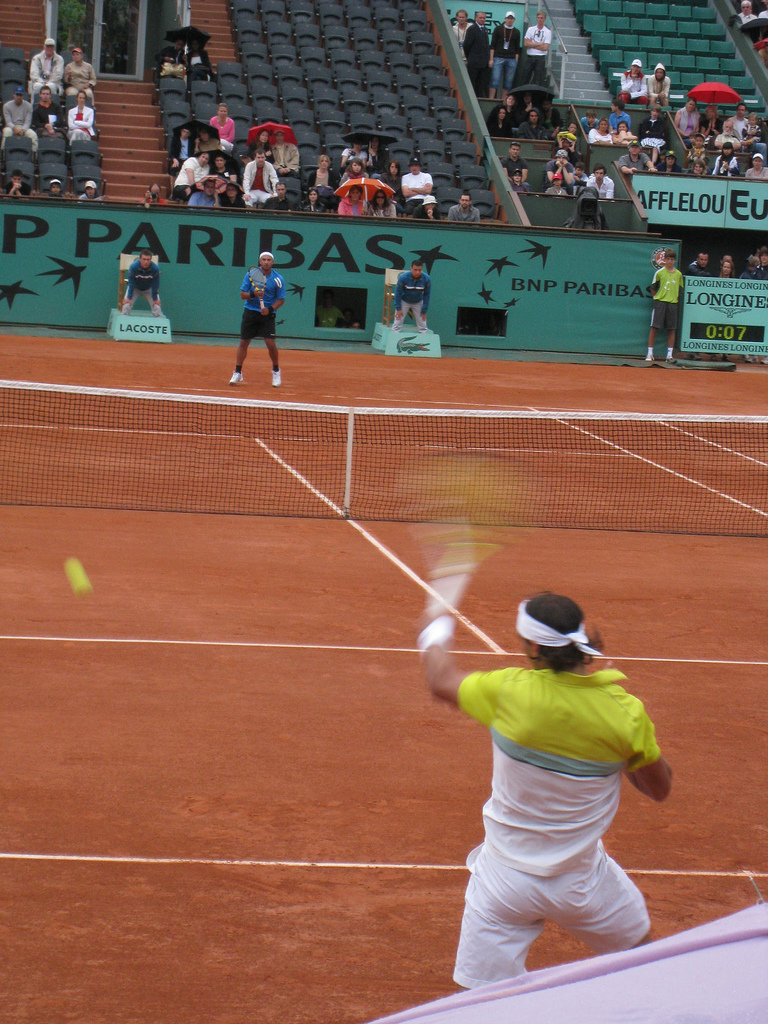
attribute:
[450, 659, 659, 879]
shirt — yellow, white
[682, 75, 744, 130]
umbrella — red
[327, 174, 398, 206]
umbrella — red, white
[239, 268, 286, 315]
shirt — blue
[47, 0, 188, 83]
door — glass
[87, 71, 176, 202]
stairs — red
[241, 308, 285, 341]
shorts — black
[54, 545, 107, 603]
tennis ball — flying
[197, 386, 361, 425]
edge — white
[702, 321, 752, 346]
timer — digital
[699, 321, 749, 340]
numbers — yellow